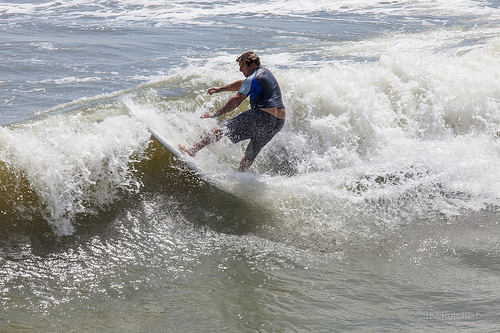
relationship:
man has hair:
[185, 41, 296, 180] [231, 49, 262, 65]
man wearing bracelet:
[185, 41, 296, 180] [211, 111, 221, 117]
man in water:
[185, 41, 296, 180] [0, 2, 498, 331]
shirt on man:
[233, 71, 295, 109] [185, 41, 296, 180]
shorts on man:
[212, 104, 286, 165] [185, 41, 296, 180]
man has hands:
[185, 41, 296, 180] [200, 83, 225, 121]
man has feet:
[185, 41, 296, 180] [173, 142, 262, 195]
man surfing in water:
[185, 41, 296, 180] [0, 2, 498, 331]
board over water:
[114, 99, 284, 204] [0, 2, 498, 331]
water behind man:
[0, 2, 498, 331] [185, 41, 296, 180]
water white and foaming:
[0, 2, 498, 331] [309, 77, 432, 169]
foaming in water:
[309, 77, 432, 169] [0, 2, 498, 331]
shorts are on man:
[212, 104, 286, 165] [185, 41, 296, 180]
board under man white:
[114, 99, 284, 204] [157, 136, 179, 155]